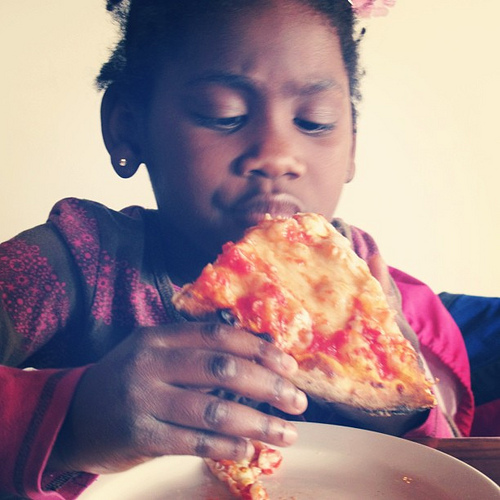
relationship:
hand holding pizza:
[40, 319, 310, 479] [172, 210, 443, 420]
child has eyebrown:
[0, 3, 481, 489] [183, 69, 267, 96]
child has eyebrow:
[0, 3, 481, 489] [185, 71, 263, 99]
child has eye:
[0, 3, 481, 489] [200, 110, 251, 136]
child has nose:
[0, 3, 481, 489] [237, 125, 305, 180]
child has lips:
[0, 3, 481, 489] [213, 194, 308, 232]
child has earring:
[0, 3, 481, 489] [101, 146, 146, 179]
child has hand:
[0, 3, 481, 489] [40, 319, 310, 479]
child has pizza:
[0, 3, 481, 489] [172, 210, 443, 420]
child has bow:
[0, 3, 481, 489] [347, 2, 408, 25]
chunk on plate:
[203, 435, 285, 500] [47, 413, 498, 499]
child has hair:
[0, 3, 481, 489] [78, 0, 371, 90]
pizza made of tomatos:
[172, 210, 443, 420] [296, 310, 364, 362]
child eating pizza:
[0, 3, 481, 489] [172, 210, 443, 420]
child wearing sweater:
[0, 3, 481, 489] [3, 199, 475, 500]